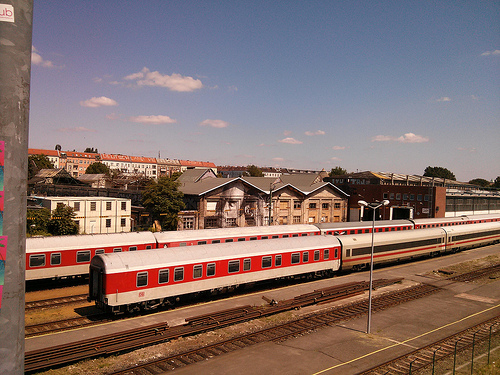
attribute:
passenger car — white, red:
[72, 224, 352, 317]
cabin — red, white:
[84, 232, 340, 308]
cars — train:
[89, 222, 499, 308]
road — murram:
[165, 276, 497, 373]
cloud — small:
[124, 63, 209, 98]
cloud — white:
[120, 47, 211, 105]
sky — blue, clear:
[28, 0, 499, 181]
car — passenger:
[26, 251, 336, 301]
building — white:
[177, 172, 369, 235]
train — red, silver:
[85, 194, 490, 336]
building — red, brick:
[90, 114, 389, 243]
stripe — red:
[106, 245, 341, 295]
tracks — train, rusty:
[25, 262, 498, 372]